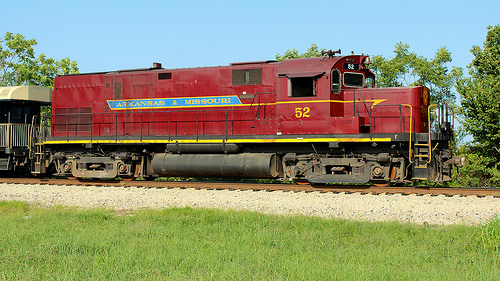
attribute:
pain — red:
[88, 105, 259, 127]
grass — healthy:
[0, 209, 499, 279]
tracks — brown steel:
[422, 183, 499, 196]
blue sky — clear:
[1, 0, 486, 33]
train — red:
[43, 49, 469, 186]